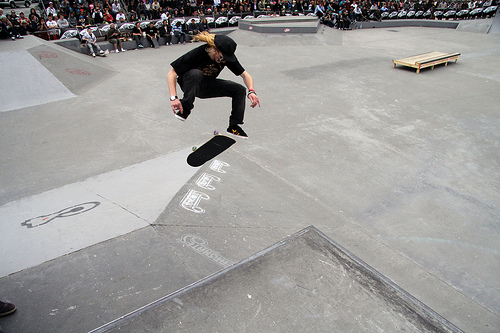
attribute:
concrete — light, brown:
[304, 84, 490, 245]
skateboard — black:
[165, 132, 240, 187]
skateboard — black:
[192, 135, 259, 175]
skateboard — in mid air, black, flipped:
[185, 129, 237, 168]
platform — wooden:
[372, 44, 490, 111]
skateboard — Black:
[182, 129, 239, 169]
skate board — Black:
[189, 131, 234, 167]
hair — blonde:
[194, 16, 216, 48]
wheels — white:
[209, 125, 221, 141]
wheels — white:
[185, 141, 197, 153]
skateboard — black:
[166, 129, 248, 174]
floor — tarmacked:
[10, 28, 499, 328]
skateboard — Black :
[179, 125, 242, 178]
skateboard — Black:
[182, 125, 235, 174]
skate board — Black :
[179, 132, 236, 169]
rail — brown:
[402, 47, 454, 71]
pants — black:
[175, 67, 245, 125]